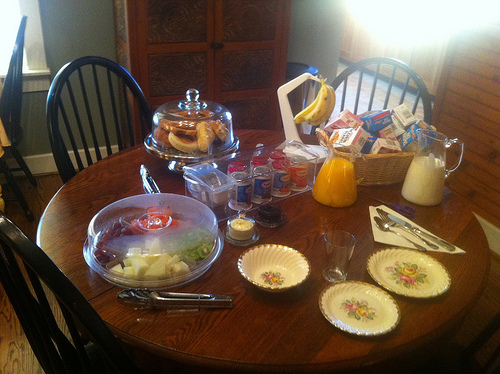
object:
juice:
[310, 156, 359, 210]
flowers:
[337, 296, 378, 322]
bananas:
[303, 74, 329, 124]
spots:
[321, 94, 329, 103]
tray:
[142, 134, 239, 163]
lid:
[144, 87, 233, 156]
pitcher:
[396, 128, 462, 207]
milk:
[397, 154, 445, 207]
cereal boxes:
[396, 120, 434, 155]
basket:
[311, 124, 433, 187]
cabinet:
[114, 0, 288, 148]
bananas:
[290, 74, 322, 125]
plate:
[317, 279, 403, 339]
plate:
[364, 246, 453, 299]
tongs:
[114, 288, 236, 311]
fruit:
[92, 218, 142, 267]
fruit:
[163, 224, 216, 264]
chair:
[43, 53, 151, 184]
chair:
[0, 212, 139, 372]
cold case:
[182, 138, 317, 220]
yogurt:
[226, 169, 251, 212]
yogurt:
[288, 156, 310, 194]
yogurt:
[268, 159, 290, 198]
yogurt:
[249, 166, 273, 206]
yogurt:
[224, 160, 247, 176]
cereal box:
[326, 125, 371, 153]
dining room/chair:
[0, 2, 499, 373]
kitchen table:
[34, 129, 490, 369]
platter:
[142, 89, 240, 175]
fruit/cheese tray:
[128, 203, 179, 236]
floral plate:
[316, 278, 399, 338]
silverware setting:
[366, 205, 465, 255]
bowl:
[235, 242, 311, 293]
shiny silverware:
[369, 216, 427, 255]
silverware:
[373, 207, 437, 250]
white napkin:
[366, 204, 466, 256]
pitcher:
[308, 138, 359, 209]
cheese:
[108, 236, 188, 290]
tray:
[79, 229, 224, 292]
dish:
[142, 134, 238, 172]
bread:
[151, 109, 227, 151]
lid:
[82, 190, 222, 289]